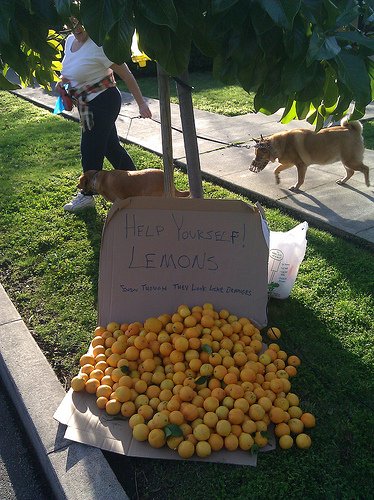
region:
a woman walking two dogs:
[51, 21, 373, 212]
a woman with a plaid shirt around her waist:
[64, 73, 122, 130]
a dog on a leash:
[134, 111, 273, 172]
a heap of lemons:
[71, 302, 318, 458]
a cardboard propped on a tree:
[100, 198, 272, 331]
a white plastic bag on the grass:
[269, 215, 309, 304]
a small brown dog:
[73, 165, 190, 204]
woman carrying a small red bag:
[56, 84, 75, 110]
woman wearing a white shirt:
[59, 33, 118, 101]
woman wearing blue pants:
[79, 87, 138, 170]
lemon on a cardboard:
[196, 440, 215, 457]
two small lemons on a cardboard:
[176, 437, 214, 458]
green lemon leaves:
[163, 424, 184, 436]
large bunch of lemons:
[69, 301, 319, 460]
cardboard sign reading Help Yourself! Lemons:
[117, 211, 251, 273]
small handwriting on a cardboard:
[117, 280, 250, 294]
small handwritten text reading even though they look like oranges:
[117, 281, 251, 296]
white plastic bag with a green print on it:
[257, 211, 308, 297]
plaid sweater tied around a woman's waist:
[67, 71, 120, 132]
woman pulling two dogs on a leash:
[58, 0, 334, 201]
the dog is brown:
[70, 167, 182, 208]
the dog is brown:
[251, 135, 337, 184]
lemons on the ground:
[66, 300, 148, 363]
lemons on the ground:
[167, 307, 309, 428]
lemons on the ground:
[69, 301, 232, 403]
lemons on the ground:
[192, 346, 311, 474]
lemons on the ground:
[68, 345, 265, 459]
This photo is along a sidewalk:
[6, 4, 349, 374]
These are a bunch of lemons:
[84, 307, 205, 397]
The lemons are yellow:
[104, 320, 262, 496]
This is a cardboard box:
[83, 177, 353, 365]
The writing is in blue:
[85, 205, 302, 356]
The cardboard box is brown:
[91, 190, 353, 360]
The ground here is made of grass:
[300, 348, 372, 470]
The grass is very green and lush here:
[302, 327, 358, 439]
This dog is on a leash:
[59, 125, 180, 214]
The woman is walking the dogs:
[46, 10, 157, 206]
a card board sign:
[82, 206, 266, 325]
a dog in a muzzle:
[250, 116, 362, 177]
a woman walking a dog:
[54, 22, 133, 215]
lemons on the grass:
[50, 307, 343, 451]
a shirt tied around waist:
[60, 73, 116, 123]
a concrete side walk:
[221, 104, 287, 182]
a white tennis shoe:
[61, 186, 96, 218]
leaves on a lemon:
[193, 366, 212, 395]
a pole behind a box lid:
[151, 4, 223, 185]